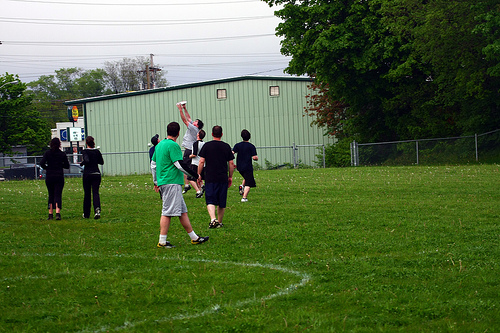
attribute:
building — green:
[63, 74, 342, 175]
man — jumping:
[176, 101, 204, 198]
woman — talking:
[39, 136, 70, 218]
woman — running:
[78, 136, 104, 220]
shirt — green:
[151, 137, 194, 186]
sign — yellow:
[70, 103, 80, 122]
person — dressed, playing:
[232, 128, 258, 204]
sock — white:
[158, 233, 168, 243]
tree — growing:
[0, 73, 51, 154]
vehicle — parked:
[2, 151, 42, 182]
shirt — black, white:
[191, 140, 205, 166]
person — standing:
[38, 137, 71, 221]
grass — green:
[1, 178, 498, 329]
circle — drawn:
[5, 245, 312, 329]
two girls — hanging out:
[37, 135, 104, 220]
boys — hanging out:
[149, 98, 259, 249]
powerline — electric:
[1, 32, 282, 48]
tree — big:
[263, 0, 498, 160]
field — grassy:
[3, 165, 498, 332]